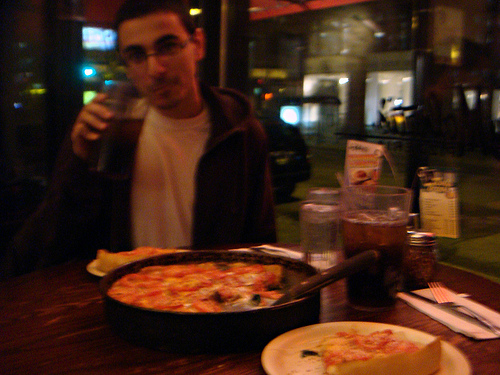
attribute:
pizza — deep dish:
[121, 258, 286, 312]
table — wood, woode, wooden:
[4, 237, 499, 374]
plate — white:
[258, 320, 475, 373]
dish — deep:
[101, 262, 323, 327]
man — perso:
[30, 1, 271, 242]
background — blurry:
[212, 4, 495, 94]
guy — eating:
[50, 4, 287, 242]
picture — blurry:
[2, 3, 500, 369]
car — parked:
[248, 103, 313, 212]